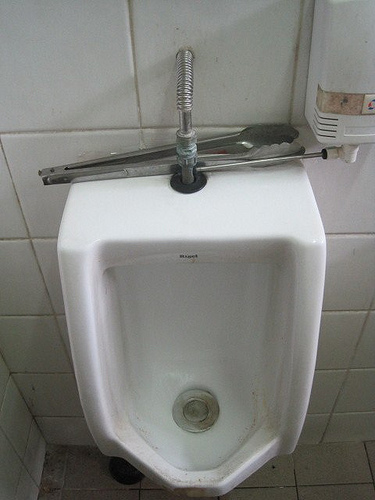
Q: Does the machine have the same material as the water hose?
A: No, the machine is made of plastic and the water hose is made of metal.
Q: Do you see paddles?
A: No, there are no paddles.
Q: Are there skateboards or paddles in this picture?
A: No, there are no paddles or skateboards.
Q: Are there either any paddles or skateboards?
A: No, there are no paddles or skateboards.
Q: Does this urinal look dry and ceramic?
A: Yes, the urinal is dry and ceramic.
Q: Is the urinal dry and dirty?
A: Yes, the urinal is dry and dirty.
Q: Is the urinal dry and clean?
A: No, the urinal is dry but dirty.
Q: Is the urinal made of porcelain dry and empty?
A: Yes, the urinal is dry and empty.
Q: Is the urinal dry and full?
A: No, the urinal is dry but empty.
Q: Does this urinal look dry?
A: Yes, the urinal is dry.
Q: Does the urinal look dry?
A: Yes, the urinal is dry.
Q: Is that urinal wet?
A: No, the urinal is dry.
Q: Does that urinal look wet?
A: No, the urinal is dry.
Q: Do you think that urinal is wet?
A: No, the urinal is dry.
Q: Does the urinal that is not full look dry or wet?
A: The urinal is dry.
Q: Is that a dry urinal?
A: Yes, that is a dry urinal.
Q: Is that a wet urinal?
A: No, that is a dry urinal.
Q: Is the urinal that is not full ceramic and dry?
A: Yes, the urinal is ceramic and dry.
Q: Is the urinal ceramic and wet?
A: No, the urinal is ceramic but dry.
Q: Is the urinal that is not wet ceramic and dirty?
A: Yes, the urinal is ceramic and dirty.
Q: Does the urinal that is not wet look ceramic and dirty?
A: Yes, the urinal is ceramic and dirty.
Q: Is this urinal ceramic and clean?
A: No, the urinal is ceramic but dirty.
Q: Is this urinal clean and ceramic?
A: No, the urinal is ceramic but dirty.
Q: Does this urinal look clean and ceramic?
A: No, the urinal is ceramic but dirty.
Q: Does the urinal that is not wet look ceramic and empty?
A: Yes, the urinal is ceramic and empty.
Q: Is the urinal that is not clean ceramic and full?
A: No, the urinal is ceramic but empty.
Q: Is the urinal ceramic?
A: Yes, the urinal is ceramic.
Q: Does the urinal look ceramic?
A: Yes, the urinal is ceramic.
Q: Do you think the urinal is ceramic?
A: Yes, the urinal is ceramic.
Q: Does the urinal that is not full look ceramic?
A: Yes, the urinal is ceramic.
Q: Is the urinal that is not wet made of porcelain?
A: Yes, the urinal is made of porcelain.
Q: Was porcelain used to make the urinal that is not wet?
A: Yes, the urinal is made of porcelain.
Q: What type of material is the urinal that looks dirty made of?
A: The urinal is made of porcelain.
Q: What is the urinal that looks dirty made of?
A: The urinal is made of porcelain.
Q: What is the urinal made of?
A: The urinal is made of porcelain.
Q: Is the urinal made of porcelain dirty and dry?
A: Yes, the urinal is dirty and dry.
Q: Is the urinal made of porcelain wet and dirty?
A: No, the urinal is dirty but dry.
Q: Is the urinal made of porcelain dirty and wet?
A: No, the urinal is dirty but dry.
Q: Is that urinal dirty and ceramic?
A: Yes, the urinal is dirty and ceramic.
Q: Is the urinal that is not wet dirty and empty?
A: Yes, the urinal is dirty and empty.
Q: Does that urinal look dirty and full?
A: No, the urinal is dirty but empty.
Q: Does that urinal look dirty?
A: Yes, the urinal is dirty.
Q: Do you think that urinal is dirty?
A: Yes, the urinal is dirty.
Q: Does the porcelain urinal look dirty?
A: Yes, the urinal is dirty.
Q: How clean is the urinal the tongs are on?
A: The urinal is dirty.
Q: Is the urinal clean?
A: No, the urinal is dirty.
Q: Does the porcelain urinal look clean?
A: No, the urinal is dirty.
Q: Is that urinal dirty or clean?
A: The urinal is dirty.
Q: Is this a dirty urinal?
A: Yes, this is a dirty urinal.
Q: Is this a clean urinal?
A: No, this is a dirty urinal.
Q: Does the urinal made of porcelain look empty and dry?
A: Yes, the urinal is empty and dry.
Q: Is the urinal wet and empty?
A: No, the urinal is empty but dry.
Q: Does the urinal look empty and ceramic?
A: Yes, the urinal is empty and ceramic.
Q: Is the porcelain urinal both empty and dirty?
A: Yes, the urinal is empty and dirty.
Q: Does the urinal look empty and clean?
A: No, the urinal is empty but dirty.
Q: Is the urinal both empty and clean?
A: No, the urinal is empty but dirty.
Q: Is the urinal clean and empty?
A: No, the urinal is empty but dirty.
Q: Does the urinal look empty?
A: Yes, the urinal is empty.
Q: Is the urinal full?
A: No, the urinal is empty.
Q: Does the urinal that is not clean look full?
A: No, the urinal is empty.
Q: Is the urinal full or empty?
A: The urinal is empty.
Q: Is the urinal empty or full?
A: The urinal is empty.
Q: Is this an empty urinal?
A: Yes, this is an empty urinal.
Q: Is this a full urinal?
A: No, this is an empty urinal.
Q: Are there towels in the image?
A: No, there are no towels.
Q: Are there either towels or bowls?
A: No, there are no towels or bowls.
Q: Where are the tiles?
A: The tiles are on the floor.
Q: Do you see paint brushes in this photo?
A: No, there are no paint brushes.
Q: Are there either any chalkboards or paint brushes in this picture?
A: No, there are no paint brushes or chalkboards.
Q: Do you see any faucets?
A: No, there are no faucets.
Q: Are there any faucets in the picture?
A: No, there are no faucets.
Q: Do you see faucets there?
A: No, there are no faucets.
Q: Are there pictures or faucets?
A: No, there are no faucets or pictures.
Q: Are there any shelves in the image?
A: No, there are no shelves.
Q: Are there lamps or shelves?
A: No, there are no shelves or lamps.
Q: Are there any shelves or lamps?
A: No, there are no shelves or lamps.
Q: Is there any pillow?
A: No, there are no pillows.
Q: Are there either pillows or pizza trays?
A: No, there are no pillows or pizza trays.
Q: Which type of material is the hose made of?
A: The hose is made of metal.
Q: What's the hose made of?
A: The hose is made of metal.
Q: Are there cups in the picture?
A: No, there are no cups.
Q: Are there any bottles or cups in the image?
A: No, there are no cups or bottles.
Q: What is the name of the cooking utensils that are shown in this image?
A: The cooking utensils are tongs.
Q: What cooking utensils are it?
A: The cooking utensils are tongs.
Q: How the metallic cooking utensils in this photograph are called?
A: The cooking utensils are tongs.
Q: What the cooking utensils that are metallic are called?
A: The cooking utensils are tongs.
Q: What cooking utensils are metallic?
A: The cooking utensils are tongs.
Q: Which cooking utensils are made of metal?
A: The cooking utensils are tongs.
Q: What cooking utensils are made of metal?
A: The cooking utensils are tongs.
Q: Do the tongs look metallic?
A: Yes, the tongs are metallic.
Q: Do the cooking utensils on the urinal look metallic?
A: Yes, the tongs are metallic.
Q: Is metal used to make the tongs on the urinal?
A: Yes, the tongs are made of metal.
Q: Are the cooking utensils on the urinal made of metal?
A: Yes, the tongs are made of metal.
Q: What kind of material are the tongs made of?
A: The tongs are made of metal.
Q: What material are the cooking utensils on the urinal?
A: The tongs are made of metal.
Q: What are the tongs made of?
A: The tongs are made of metal.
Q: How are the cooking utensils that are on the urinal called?
A: The cooking utensils are tongs.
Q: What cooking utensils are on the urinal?
A: The cooking utensils are tongs.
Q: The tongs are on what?
A: The tongs are on the urinal.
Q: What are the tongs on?
A: The tongs are on the urinal.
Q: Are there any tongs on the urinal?
A: Yes, there are tongs on the urinal.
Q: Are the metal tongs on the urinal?
A: Yes, the tongs are on the urinal.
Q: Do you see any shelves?
A: No, there are no shelves.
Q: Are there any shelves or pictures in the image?
A: No, there are no shelves or pictures.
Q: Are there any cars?
A: No, there are no cars.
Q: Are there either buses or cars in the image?
A: No, there are no cars or buses.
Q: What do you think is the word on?
A: The word is on the urinal.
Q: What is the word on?
A: The word is on the urinal.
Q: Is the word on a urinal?
A: Yes, the word is on a urinal.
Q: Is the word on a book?
A: No, the word is on a urinal.